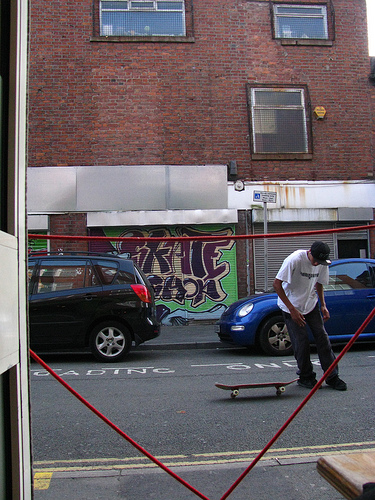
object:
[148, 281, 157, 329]
back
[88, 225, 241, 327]
graffiti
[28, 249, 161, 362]
car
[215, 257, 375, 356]
car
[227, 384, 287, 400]
wheels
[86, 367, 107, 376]
lettering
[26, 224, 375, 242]
rope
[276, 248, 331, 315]
shirt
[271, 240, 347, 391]
boy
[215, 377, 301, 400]
skateboard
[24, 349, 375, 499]
ground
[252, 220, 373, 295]
gate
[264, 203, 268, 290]
pole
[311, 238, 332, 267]
cap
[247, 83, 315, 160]
window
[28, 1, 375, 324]
building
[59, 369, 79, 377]
letters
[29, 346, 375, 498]
street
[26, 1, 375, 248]
wall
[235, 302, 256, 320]
headlight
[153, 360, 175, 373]
lettering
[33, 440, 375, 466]
lines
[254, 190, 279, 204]
marks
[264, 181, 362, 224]
trim